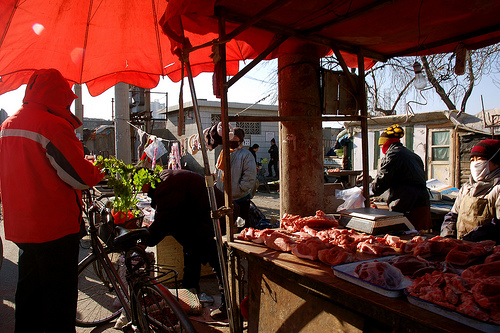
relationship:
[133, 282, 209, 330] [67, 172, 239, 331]
wheel on bike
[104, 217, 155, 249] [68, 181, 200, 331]
seat on bike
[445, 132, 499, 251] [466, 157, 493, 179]
female wearing mask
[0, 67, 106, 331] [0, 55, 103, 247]
man wearing jacket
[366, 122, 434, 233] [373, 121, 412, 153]
man wearing hat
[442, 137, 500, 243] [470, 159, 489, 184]
female wearing face mask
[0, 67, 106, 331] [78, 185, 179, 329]
man standing with bicycle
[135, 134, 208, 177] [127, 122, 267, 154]
clothes on line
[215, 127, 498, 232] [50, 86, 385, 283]
people at food market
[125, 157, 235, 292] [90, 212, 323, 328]
man fixing plats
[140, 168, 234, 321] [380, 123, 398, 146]
man wearing hat